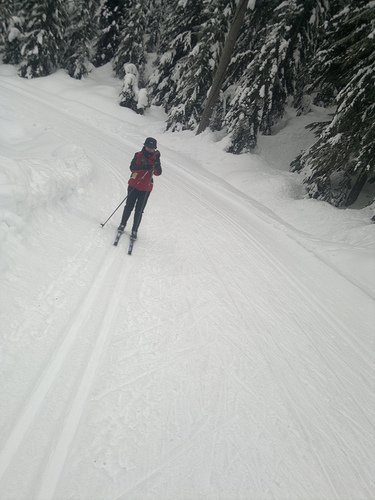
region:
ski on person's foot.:
[126, 241, 138, 261]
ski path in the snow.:
[62, 293, 111, 377]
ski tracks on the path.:
[221, 302, 266, 371]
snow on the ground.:
[245, 163, 270, 185]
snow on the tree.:
[128, 65, 145, 104]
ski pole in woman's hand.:
[94, 199, 121, 227]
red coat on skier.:
[139, 178, 147, 187]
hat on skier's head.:
[146, 137, 158, 146]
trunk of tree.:
[209, 38, 237, 89]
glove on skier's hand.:
[141, 162, 151, 173]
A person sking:
[93, 129, 174, 254]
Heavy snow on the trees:
[170, 20, 271, 121]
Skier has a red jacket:
[116, 129, 167, 193]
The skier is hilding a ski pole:
[90, 184, 134, 232]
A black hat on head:
[137, 136, 159, 151]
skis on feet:
[104, 231, 149, 251]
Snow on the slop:
[53, 281, 296, 423]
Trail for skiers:
[51, 98, 187, 178]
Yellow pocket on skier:
[121, 171, 139, 184]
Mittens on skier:
[139, 164, 150, 176]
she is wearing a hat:
[138, 134, 162, 148]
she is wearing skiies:
[109, 219, 137, 260]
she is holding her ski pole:
[93, 159, 155, 236]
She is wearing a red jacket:
[122, 152, 162, 199]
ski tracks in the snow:
[206, 199, 373, 370]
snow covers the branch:
[122, 62, 140, 107]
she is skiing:
[90, 125, 200, 271]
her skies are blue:
[126, 225, 145, 258]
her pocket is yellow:
[131, 172, 139, 183]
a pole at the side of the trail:
[177, 3, 248, 144]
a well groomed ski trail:
[36, 114, 372, 442]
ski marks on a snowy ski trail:
[22, 324, 113, 420]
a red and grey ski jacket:
[120, 143, 161, 193]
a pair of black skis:
[107, 229, 150, 256]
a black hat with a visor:
[135, 131, 165, 154]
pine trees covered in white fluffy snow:
[162, 8, 205, 130]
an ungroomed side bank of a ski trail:
[14, 118, 93, 199]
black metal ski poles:
[87, 154, 159, 233]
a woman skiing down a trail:
[17, 88, 207, 336]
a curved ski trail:
[4, 71, 211, 184]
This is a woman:
[76, 120, 174, 261]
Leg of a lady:
[99, 135, 180, 266]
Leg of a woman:
[128, 189, 153, 266]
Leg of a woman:
[110, 175, 134, 251]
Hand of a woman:
[151, 151, 170, 181]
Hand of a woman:
[122, 150, 156, 176]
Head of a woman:
[136, 131, 162, 158]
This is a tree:
[199, 1, 246, 139]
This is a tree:
[217, 9, 309, 156]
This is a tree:
[336, 6, 373, 211]